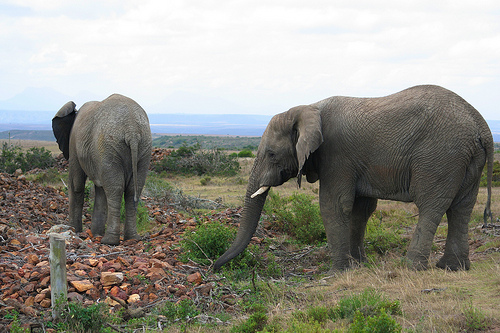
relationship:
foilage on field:
[153, 144, 241, 176] [2, 149, 498, 329]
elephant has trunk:
[213, 85, 492, 274] [237, 176, 265, 261]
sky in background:
[19, 8, 485, 115] [26, 33, 274, 135]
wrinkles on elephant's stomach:
[400, 122, 420, 195] [356, 169, 411, 206]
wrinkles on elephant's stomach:
[76, 128, 93, 172] [80, 161, 103, 187]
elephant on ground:
[241, 100, 433, 237] [4, 129, 499, 331]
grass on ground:
[341, 265, 498, 330] [4, 129, 499, 331]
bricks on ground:
[83, 255, 170, 303] [4, 129, 499, 331]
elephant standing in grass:
[213, 85, 492, 274] [4, 135, 497, 331]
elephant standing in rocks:
[77, 107, 227, 204] [39, 217, 181, 317]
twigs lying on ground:
[145, 280, 233, 318] [4, 129, 499, 331]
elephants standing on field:
[50, 82, 495, 284] [4, 129, 496, 332]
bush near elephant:
[177, 216, 236, 264] [213, 85, 492, 274]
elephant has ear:
[213, 85, 492, 274] [290, 104, 327, 190]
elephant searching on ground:
[213, 85, 492, 274] [204, 274, 480, 325]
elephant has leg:
[213, 85, 492, 274] [345, 188, 376, 265]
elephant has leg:
[213, 85, 492, 274] [318, 173, 358, 268]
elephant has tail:
[213, 85, 492, 274] [481, 134, 495, 224]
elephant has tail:
[51, 93, 151, 245] [125, 132, 145, 205]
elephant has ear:
[51, 93, 151, 245] [57, 97, 75, 159]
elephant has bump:
[213, 85, 492, 274] [314, 92, 356, 111]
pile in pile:
[477, 223, 500, 238] [475, 220, 498, 233]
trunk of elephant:
[212, 164, 274, 271] [213, 85, 492, 274]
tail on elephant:
[118, 125, 160, 209] [26, 99, 105, 198]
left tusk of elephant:
[250, 186, 270, 199] [208, 99, 496, 282]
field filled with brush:
[4, 129, 496, 332] [142, 182, 217, 209]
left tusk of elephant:
[207, 168, 318, 280] [213, 85, 492, 274]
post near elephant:
[30, 230, 84, 327] [43, 90, 153, 242]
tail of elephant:
[480, 132, 498, 224] [43, 90, 153, 242]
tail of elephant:
[125, 131, 142, 203] [213, 85, 492, 274]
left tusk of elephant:
[250, 186, 270, 199] [213, 85, 492, 274]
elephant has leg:
[213, 85, 492, 274] [403, 193, 451, 270]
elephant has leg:
[213, 85, 492, 274] [435, 189, 475, 271]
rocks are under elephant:
[0, 172, 252, 309] [51, 93, 151, 245]